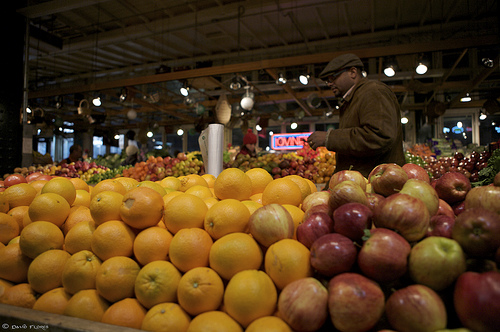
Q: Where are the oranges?
A: Next to apples.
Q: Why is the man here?
A: Shopping.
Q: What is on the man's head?
A: Cap.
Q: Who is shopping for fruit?
A: Man in brown jacket.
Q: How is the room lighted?
A: Lights on ceiling.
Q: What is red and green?
A: Apples.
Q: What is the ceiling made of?
A: Wood.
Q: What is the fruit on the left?
A: Oranges.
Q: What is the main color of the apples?
A: Red.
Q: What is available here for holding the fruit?
A: Plastic bags.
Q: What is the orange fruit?
A: Oranges.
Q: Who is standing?
A: A man.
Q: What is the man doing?
A: Looking for fruit.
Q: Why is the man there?
A: To buy food.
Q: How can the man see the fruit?
A: With his glasses.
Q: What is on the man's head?
A: A hat.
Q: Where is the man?
A: At the fruit market.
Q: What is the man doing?
A: Buying fruit.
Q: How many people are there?
A: One.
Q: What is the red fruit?
A: It is an apple.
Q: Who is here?
A: One man.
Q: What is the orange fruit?
A: It is an orange.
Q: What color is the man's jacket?
A: Brown.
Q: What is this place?
A: A fruit market.